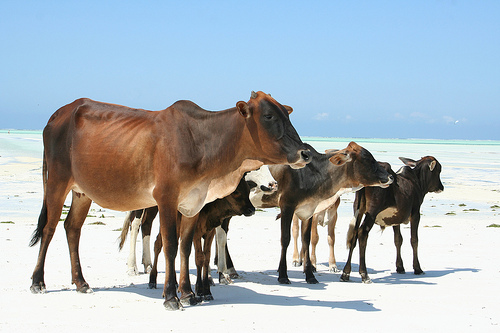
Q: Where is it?
A: This is at the beach.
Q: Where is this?
A: This is at the beach.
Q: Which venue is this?
A: This is a beach.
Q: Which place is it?
A: It is a beach.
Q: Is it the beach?
A: Yes, it is the beach.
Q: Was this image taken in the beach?
A: Yes, it was taken in the beach.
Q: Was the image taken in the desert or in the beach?
A: It was taken at the beach.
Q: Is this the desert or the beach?
A: It is the beach.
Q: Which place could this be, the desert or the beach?
A: It is the beach.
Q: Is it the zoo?
A: No, it is the beach.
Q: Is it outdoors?
A: Yes, it is outdoors.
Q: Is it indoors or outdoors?
A: It is outdoors.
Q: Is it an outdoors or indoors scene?
A: It is outdoors.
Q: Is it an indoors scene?
A: No, it is outdoors.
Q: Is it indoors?
A: No, it is outdoors.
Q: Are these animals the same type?
A: Yes, all the animals are cows.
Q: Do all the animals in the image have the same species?
A: Yes, all the animals are cows.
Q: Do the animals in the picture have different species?
A: No, all the animals are cows.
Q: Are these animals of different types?
A: No, all the animals are cows.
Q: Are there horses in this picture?
A: No, there are no horses.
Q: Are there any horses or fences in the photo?
A: No, there are no horses or fences.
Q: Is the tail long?
A: Yes, the tail is long.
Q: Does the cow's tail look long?
A: Yes, the tail is long.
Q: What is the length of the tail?
A: The tail is long.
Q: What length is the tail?
A: The tail is long.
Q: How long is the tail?
A: The tail is long.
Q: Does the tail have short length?
A: No, the tail is long.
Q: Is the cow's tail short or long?
A: The tail is long.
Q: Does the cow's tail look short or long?
A: The tail is long.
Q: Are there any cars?
A: No, there are no cars.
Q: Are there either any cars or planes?
A: No, there are no cars or planes.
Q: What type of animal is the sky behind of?
A: The sky is behind the cow.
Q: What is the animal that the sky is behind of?
A: The animal is a cow.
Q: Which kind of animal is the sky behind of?
A: The sky is behind the cow.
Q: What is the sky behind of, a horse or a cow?
A: The sky is behind a cow.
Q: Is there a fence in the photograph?
A: No, there are no fences.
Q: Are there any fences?
A: No, there are no fences.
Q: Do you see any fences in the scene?
A: No, there are no fences.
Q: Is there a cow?
A: Yes, there are cows.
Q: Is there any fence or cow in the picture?
A: Yes, there are cows.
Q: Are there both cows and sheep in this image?
A: No, there are cows but no sheep.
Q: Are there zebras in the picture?
A: No, there are no zebras.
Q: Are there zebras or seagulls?
A: No, there are no zebras or seagulls.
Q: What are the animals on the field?
A: The animals are cows.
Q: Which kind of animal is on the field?
A: The animals are cows.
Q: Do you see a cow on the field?
A: Yes, there are cows on the field.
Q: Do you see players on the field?
A: No, there are cows on the field.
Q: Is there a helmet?
A: No, there are no helmets.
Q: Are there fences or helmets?
A: No, there are no helmets or fences.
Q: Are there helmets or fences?
A: No, there are no helmets or fences.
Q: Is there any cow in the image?
A: Yes, there is a cow.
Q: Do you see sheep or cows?
A: Yes, there is a cow.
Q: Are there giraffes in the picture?
A: No, there are no giraffes.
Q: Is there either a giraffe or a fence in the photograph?
A: No, there are no giraffes or fences.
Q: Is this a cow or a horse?
A: This is a cow.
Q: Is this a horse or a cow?
A: This is a cow.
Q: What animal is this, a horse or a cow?
A: This is a cow.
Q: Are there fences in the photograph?
A: No, there are no fences.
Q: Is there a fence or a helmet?
A: No, there are no fences or helmets.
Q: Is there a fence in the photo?
A: No, there are no fences.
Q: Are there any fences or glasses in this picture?
A: No, there are no fences or glasses.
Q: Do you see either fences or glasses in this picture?
A: No, there are no fences or glasses.